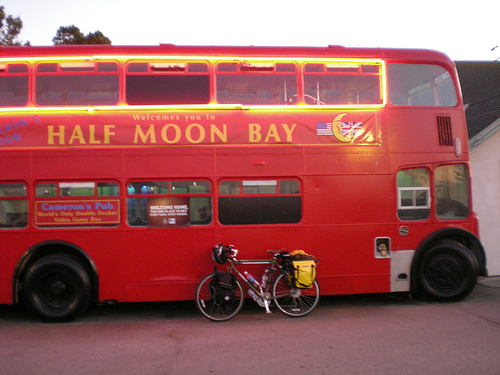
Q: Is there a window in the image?
A: Yes, there is a window.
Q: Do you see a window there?
A: Yes, there is a window.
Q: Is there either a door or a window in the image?
A: Yes, there is a window.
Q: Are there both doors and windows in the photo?
A: No, there is a window but no doors.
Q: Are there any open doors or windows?
A: Yes, there is an open window.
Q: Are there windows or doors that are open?
A: Yes, the window is open.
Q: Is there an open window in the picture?
A: Yes, there is an open window.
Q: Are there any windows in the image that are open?
A: Yes, there is a window that is open.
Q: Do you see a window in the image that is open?
A: Yes, there is a window that is open.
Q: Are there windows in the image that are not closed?
A: Yes, there is a open window.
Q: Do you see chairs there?
A: No, there are no chairs.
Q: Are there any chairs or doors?
A: No, there are no chairs or doors.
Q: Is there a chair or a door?
A: No, there are no chairs or doors.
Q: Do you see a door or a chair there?
A: No, there are no chairs or doors.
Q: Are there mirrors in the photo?
A: No, there are no mirrors.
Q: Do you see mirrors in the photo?
A: No, there are no mirrors.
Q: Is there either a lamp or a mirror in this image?
A: No, there are no mirrors or lamps.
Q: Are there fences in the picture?
A: No, there are no fences.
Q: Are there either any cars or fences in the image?
A: No, there are no fences or cars.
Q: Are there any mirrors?
A: No, there are no mirrors.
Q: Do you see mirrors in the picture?
A: No, there are no mirrors.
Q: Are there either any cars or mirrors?
A: No, there are no mirrors or cars.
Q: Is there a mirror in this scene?
A: No, there are no mirrors.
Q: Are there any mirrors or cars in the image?
A: No, there are no mirrors or cars.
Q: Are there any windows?
A: Yes, there is a window.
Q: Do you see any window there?
A: Yes, there is a window.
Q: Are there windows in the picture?
A: Yes, there is a window.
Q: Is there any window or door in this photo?
A: Yes, there is a window.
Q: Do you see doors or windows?
A: Yes, there is a window.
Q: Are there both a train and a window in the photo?
A: No, there is a window but no trains.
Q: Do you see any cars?
A: No, there are no cars.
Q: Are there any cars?
A: No, there are no cars.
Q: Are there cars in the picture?
A: No, there are no cars.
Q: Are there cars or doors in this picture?
A: No, there are no cars or doors.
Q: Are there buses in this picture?
A: Yes, there is a bus.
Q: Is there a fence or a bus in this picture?
A: Yes, there is a bus.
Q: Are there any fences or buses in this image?
A: Yes, there is a bus.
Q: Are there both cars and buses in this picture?
A: No, there is a bus but no cars.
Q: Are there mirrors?
A: No, there are no mirrors.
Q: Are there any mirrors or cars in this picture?
A: No, there are no mirrors or cars.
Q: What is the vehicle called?
A: The vehicle is a bus.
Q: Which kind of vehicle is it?
A: The vehicle is a bus.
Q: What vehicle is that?
A: This is a bus.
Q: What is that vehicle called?
A: This is a bus.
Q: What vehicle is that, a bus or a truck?
A: This is a bus.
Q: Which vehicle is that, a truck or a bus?
A: This is a bus.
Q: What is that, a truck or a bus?
A: That is a bus.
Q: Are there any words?
A: Yes, there are words.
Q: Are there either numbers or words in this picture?
A: Yes, there are words.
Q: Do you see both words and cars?
A: No, there are words but no cars.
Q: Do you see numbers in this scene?
A: No, there are no numbers.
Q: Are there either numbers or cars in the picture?
A: No, there are no numbers or cars.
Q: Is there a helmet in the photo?
A: Yes, there is a helmet.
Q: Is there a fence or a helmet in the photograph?
A: Yes, there is a helmet.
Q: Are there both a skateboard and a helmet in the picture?
A: No, there is a helmet but no skateboards.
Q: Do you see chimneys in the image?
A: No, there are no chimneys.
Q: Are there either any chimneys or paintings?
A: No, there are no chimneys or paintings.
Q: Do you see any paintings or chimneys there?
A: No, there are no chimneys or paintings.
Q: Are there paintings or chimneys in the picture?
A: No, there are no chimneys or paintings.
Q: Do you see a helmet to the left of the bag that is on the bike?
A: Yes, there is a helmet to the left of the bag.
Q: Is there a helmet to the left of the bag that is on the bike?
A: Yes, there is a helmet to the left of the bag.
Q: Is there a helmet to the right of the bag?
A: No, the helmet is to the left of the bag.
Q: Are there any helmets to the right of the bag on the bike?
A: No, the helmet is to the left of the bag.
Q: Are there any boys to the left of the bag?
A: No, there is a helmet to the left of the bag.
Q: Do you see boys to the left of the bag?
A: No, there is a helmet to the left of the bag.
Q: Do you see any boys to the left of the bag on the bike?
A: No, there is a helmet to the left of the bag.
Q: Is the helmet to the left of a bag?
A: Yes, the helmet is to the left of a bag.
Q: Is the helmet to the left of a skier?
A: No, the helmet is to the left of a bag.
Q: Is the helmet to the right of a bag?
A: No, the helmet is to the left of a bag.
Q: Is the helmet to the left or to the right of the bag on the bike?
A: The helmet is to the left of the bag.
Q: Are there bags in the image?
A: Yes, there is a bag.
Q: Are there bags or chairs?
A: Yes, there is a bag.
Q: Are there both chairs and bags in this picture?
A: No, there is a bag but no chairs.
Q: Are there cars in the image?
A: No, there are no cars.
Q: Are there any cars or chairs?
A: No, there are no cars or chairs.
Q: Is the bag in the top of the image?
A: No, the bag is in the bottom of the image.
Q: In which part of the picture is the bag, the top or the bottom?
A: The bag is in the bottom of the image.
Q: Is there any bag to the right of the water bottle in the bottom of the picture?
A: Yes, there is a bag to the right of the water bottle.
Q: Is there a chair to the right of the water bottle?
A: No, there is a bag to the right of the water bottle.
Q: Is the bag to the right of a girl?
A: No, the bag is to the right of the water bottle.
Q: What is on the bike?
A: The bag is on the bike.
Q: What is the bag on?
A: The bag is on the bike.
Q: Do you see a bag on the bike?
A: Yes, there is a bag on the bike.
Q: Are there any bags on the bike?
A: Yes, there is a bag on the bike.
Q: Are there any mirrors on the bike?
A: No, there is a bag on the bike.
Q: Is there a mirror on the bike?
A: No, there is a bag on the bike.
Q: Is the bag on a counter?
A: No, the bag is on the bike.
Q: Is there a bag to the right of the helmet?
A: Yes, there is a bag to the right of the helmet.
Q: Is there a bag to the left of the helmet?
A: No, the bag is to the right of the helmet.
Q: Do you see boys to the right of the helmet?
A: No, there is a bag to the right of the helmet.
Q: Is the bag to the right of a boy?
A: No, the bag is to the right of the helmet.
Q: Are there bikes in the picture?
A: Yes, there is a bike.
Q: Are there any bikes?
A: Yes, there is a bike.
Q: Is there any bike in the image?
A: Yes, there is a bike.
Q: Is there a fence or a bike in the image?
A: Yes, there is a bike.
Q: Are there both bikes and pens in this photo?
A: No, there is a bike but no pens.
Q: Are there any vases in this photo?
A: No, there are no vases.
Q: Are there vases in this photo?
A: No, there are no vases.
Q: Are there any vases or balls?
A: No, there are no vases or balls.